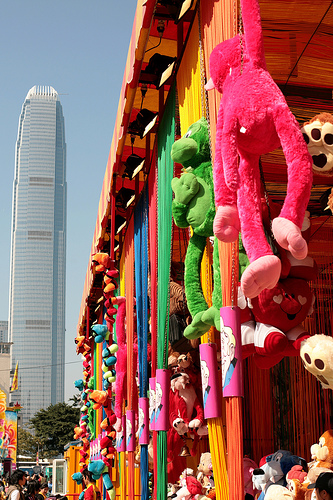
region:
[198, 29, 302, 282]
a pink toy monkey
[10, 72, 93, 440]
a tall building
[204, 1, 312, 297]
pink stuffed monkey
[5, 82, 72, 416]
tall skyscraper building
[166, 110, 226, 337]
green monkey stuffed animal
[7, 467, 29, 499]
man with black hair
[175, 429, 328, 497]
stuffed animals on display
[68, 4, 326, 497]
hanging stuffed animals on display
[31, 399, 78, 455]
tree with green leaves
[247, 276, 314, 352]
heart shaped stuffed animal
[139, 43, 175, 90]
black overhead light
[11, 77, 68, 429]
tall white and blue building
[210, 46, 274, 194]
pink stuffed monkey on booth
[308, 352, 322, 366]
white and black paw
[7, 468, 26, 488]
person with short black hair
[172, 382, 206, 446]
red and white stuffed animal hanging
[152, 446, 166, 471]
green curtain hanging up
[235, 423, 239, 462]
peach curtain hanging up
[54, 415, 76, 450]
green tree in distance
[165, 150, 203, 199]
green stuffed animal hanging up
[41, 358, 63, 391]
very tall skyscraper in distance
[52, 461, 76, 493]
white framed object in distance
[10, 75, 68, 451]
a tall building in the background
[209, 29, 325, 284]
a stuffed pink monkey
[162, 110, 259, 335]
green monkey holding his chest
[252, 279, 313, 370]
a stuffed toy shaped like a heart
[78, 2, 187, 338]
lights above the animal stand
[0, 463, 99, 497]
people shopping for stuffed animals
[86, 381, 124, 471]
a red and white snake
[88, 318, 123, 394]
a blue and green snake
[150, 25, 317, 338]
two stuffed monkeys toys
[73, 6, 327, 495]
a store selling stuffed animals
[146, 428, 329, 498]
A bunch of stuffed animals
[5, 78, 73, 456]
A tall narrow building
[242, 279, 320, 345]
A stuffed heart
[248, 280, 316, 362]
The heart has hearts on its face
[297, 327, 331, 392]
A large animal paw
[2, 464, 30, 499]
A person looking at the stuffed animals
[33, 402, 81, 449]
A green tree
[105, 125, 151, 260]
A row of lights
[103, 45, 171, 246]
The lights are turned on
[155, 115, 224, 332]
Animal has a paw on its chest